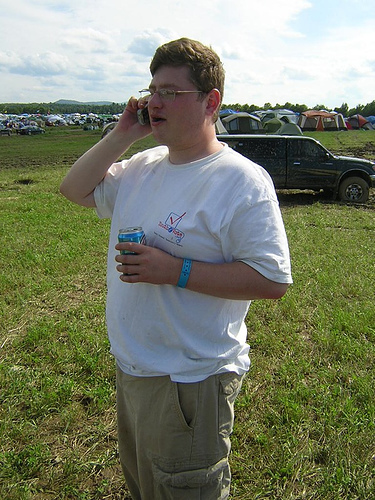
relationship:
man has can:
[58, 38, 292, 499] [116, 226, 146, 277]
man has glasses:
[58, 38, 292, 499] [138, 88, 211, 104]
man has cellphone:
[58, 38, 292, 499] [135, 94, 152, 127]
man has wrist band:
[58, 38, 292, 499] [176, 258, 193, 287]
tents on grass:
[0, 110, 374, 138] [307, 313, 373, 400]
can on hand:
[116, 226, 146, 277] [114, 239, 171, 288]